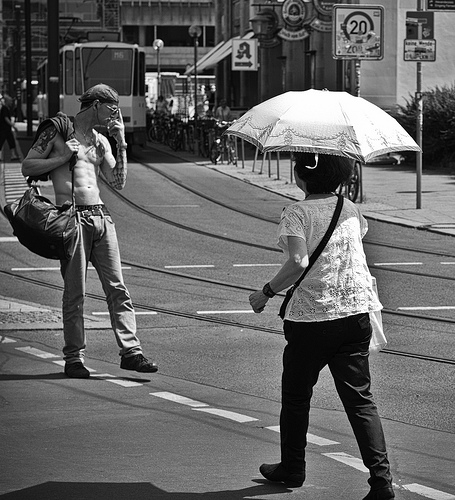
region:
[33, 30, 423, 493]
Some people are walking in the city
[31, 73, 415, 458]
Some people are carrying an umbrella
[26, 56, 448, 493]
Some people are casting a shadow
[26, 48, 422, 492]
Some people are not wearing a shirt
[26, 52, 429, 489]
Some people are going to work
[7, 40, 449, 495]
Some people are carrying a bag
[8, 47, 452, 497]
Some people are out in the sunshine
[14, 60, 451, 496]
Some people are enjoying the day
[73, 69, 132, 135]
head of a person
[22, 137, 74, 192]
arm of a person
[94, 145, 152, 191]
arm of a person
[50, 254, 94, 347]
leg of a person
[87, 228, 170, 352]
leg of a person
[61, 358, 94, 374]
feet of a person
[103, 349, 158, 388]
feet of a person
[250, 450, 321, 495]
feet of a person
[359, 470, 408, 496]
feet of a person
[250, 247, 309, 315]
arm of a person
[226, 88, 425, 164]
Canopy of a light umbrella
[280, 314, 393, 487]
Dark planes on a woman's legs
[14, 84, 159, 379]
Shirtless man on the street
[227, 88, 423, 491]
A woman holding an umbrella, crossing the street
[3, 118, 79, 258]
A bag hanging from a man's shoulder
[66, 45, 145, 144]
Front end of a trolley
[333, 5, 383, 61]
A square sign with rounded corners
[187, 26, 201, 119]
A streetlamp in the day time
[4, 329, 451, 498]
Segmented line painted on the street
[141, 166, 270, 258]
Trolley tracks embedded in the road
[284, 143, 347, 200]
head of a person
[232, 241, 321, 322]
arm of a person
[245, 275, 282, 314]
hand of a person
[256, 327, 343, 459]
leg of a person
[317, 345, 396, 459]
leg of a person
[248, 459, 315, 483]
feet of a person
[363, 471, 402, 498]
feet of a person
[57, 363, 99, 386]
feet of a person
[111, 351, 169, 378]
feet of a person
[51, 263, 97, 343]
leg of a person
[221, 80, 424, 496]
Woman holding an umbrella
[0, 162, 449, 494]
White lines on the road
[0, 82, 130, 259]
A man carrying a bag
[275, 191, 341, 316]
A black bag strap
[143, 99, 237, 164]
Many bicycles have been parked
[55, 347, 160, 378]
A pair of shoes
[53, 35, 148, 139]
The front of a vehicle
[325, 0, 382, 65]
A sign with number "20" on it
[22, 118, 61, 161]
A tattoo on an arm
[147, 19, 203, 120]
Two tall street lamps